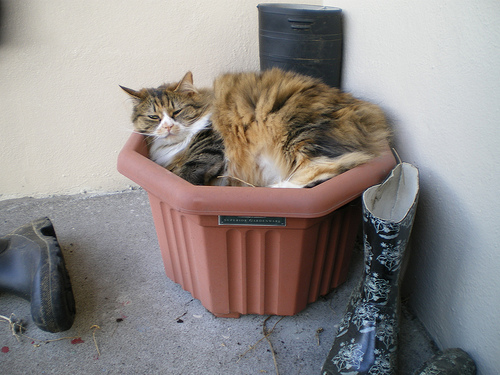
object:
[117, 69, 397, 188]
cat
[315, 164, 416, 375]
boot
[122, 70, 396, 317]
holder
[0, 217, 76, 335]
boot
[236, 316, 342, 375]
twigs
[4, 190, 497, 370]
ground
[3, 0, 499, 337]
wall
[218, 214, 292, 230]
imprint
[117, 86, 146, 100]
ears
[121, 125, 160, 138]
whiskers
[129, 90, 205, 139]
face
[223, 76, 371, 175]
fur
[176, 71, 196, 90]
ear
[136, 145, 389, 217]
down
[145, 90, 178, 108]
stripes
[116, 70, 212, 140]
head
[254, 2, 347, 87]
boot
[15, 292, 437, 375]
dirt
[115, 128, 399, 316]
pot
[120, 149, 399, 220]
lip